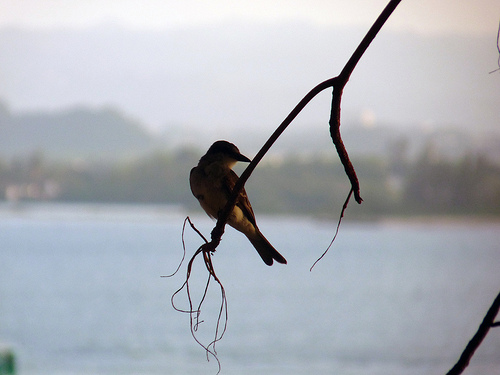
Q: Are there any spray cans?
A: No, there are no spray cans.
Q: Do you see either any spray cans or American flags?
A: No, there are no spray cans or American flags.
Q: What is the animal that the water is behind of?
A: The animal is a bird.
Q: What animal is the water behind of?
A: The water is behind the bird.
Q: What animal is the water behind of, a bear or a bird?
A: The water is behind a bird.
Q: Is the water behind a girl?
A: No, the water is behind a bird.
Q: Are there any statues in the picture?
A: No, there are no statues.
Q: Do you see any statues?
A: No, there are no statues.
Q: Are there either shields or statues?
A: No, there are no statues or shields.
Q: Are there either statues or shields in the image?
A: No, there are no statues or shields.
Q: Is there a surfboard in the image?
A: No, there are no surfboards.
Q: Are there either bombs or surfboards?
A: No, there are no surfboards or bombs.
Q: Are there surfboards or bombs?
A: No, there are no surfboards or bombs.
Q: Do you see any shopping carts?
A: No, there are no shopping carts.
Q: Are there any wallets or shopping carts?
A: No, there are no shopping carts or wallets.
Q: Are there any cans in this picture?
A: No, there are no cans.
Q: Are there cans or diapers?
A: No, there are no cans or diapers.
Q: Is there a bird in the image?
A: Yes, there is a bird.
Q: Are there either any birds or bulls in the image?
A: Yes, there is a bird.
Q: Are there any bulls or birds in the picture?
A: Yes, there is a bird.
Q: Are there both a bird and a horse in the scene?
A: No, there is a bird but no horses.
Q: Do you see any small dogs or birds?
A: Yes, there is a small bird.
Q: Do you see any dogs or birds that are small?
A: Yes, the bird is small.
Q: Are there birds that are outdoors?
A: Yes, there is a bird that is outdoors.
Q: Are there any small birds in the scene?
A: Yes, there is a small bird.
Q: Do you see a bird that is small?
A: Yes, there is a small bird.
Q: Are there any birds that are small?
A: Yes, there is a bird that is small.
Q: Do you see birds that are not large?
A: Yes, there is a small bird.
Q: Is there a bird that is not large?
A: Yes, there is a small bird.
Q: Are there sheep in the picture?
A: No, there are no sheep.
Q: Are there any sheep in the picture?
A: No, there are no sheep.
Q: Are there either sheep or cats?
A: No, there are no sheep or cats.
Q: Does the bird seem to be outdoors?
A: Yes, the bird is outdoors.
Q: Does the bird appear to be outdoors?
A: Yes, the bird is outdoors.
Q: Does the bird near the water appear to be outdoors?
A: Yes, the bird is outdoors.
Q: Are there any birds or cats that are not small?
A: No, there is a bird but it is small.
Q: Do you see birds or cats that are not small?
A: No, there is a bird but it is small.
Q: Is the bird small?
A: Yes, the bird is small.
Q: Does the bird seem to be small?
A: Yes, the bird is small.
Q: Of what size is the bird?
A: The bird is small.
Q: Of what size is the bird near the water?
A: The bird is small.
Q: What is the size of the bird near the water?
A: The bird is small.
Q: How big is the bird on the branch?
A: The bird is small.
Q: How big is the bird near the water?
A: The bird is small.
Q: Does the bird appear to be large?
A: No, the bird is small.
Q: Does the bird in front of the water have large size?
A: No, the bird is small.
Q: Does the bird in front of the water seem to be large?
A: No, the bird is small.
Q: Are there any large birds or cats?
A: No, there is a bird but it is small.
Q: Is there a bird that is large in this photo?
A: No, there is a bird but it is small.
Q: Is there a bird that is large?
A: No, there is a bird but it is small.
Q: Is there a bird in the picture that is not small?
A: No, there is a bird but it is small.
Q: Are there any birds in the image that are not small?
A: No, there is a bird but it is small.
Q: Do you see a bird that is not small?
A: No, there is a bird but it is small.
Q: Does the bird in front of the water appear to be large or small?
A: The bird is small.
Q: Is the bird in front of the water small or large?
A: The bird is small.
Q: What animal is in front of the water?
A: The bird is in front of the water.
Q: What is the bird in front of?
A: The bird is in front of the water.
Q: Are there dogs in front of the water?
A: No, there is a bird in front of the water.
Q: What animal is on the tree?
A: The bird is on the tree.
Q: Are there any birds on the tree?
A: Yes, there is a bird on the tree.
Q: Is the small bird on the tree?
A: Yes, the bird is on the tree.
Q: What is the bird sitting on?
A: The bird is sitting on the branch.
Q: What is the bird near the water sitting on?
A: The bird is sitting on the branch.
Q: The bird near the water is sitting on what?
A: The bird is sitting on the branch.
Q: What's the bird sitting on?
A: The bird is sitting on the branch.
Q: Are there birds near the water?
A: Yes, there is a bird near the water.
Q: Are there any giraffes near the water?
A: No, there is a bird near the water.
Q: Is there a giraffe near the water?
A: No, there is a bird near the water.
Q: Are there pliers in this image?
A: No, there are no pliers.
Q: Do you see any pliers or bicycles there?
A: No, there are no pliers or bicycles.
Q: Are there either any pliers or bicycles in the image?
A: No, there are no pliers or bicycles.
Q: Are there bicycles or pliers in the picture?
A: No, there are no pliers or bicycles.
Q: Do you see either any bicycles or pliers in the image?
A: No, there are no pliers or bicycles.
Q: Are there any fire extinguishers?
A: No, there are no fire extinguishers.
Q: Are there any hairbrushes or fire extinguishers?
A: No, there are no fire extinguishers or hairbrushes.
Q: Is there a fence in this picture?
A: No, there are no fences.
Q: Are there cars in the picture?
A: No, there are no cars.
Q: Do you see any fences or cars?
A: No, there are no cars or fences.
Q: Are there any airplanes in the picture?
A: No, there are no airplanes.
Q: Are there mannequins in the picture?
A: No, there are no mannequins.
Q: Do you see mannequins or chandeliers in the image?
A: No, there are no mannequins or chandeliers.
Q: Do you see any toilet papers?
A: No, there are no toilet papers.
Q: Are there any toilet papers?
A: No, there are no toilet papers.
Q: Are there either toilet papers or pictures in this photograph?
A: No, there are no toilet papers or pictures.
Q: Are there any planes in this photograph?
A: No, there are no planes.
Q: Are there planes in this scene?
A: No, there are no planes.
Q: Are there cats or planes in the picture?
A: No, there are no planes or cats.